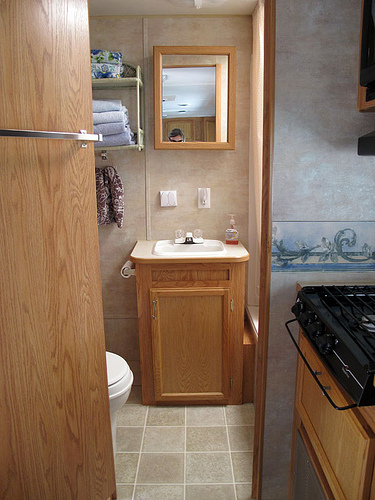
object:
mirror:
[153, 46, 235, 151]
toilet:
[106, 350, 135, 459]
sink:
[151, 237, 225, 256]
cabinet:
[128, 236, 250, 408]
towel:
[92, 96, 122, 112]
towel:
[92, 109, 128, 126]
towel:
[88, 121, 129, 135]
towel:
[95, 132, 133, 149]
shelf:
[87, 143, 144, 153]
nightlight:
[200, 188, 208, 206]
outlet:
[197, 188, 211, 209]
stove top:
[296, 279, 373, 376]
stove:
[283, 283, 373, 414]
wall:
[86, 13, 249, 385]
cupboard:
[149, 279, 232, 405]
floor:
[116, 383, 256, 499]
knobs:
[298, 310, 314, 330]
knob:
[316, 334, 333, 356]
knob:
[308, 324, 322, 342]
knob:
[290, 300, 305, 320]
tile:
[184, 405, 226, 428]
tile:
[185, 426, 228, 453]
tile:
[185, 452, 234, 484]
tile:
[142, 426, 185, 453]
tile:
[135, 452, 184, 485]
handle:
[150, 299, 158, 319]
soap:
[225, 213, 239, 245]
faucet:
[174, 223, 205, 245]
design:
[272, 219, 375, 272]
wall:
[262, 8, 373, 498]